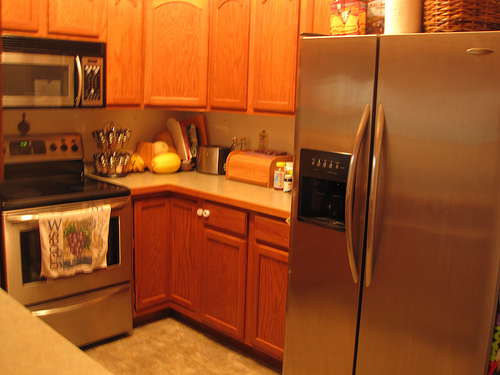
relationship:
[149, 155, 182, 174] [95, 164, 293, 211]
fruit on counter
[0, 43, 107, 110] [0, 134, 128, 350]
microwave above oven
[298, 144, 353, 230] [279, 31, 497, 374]
ice &water dispenser on fridge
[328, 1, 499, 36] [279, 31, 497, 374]
items on top of fridge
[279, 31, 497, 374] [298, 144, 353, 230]
fridge has ice &water dispenser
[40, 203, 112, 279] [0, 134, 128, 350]
towel hanging in front of oven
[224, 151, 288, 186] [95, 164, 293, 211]
bread box on counter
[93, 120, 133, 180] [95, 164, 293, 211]
spice rack on counter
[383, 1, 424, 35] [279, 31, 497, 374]
paper towel on top of fridge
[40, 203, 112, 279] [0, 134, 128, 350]
towel on oven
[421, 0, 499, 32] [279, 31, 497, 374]
basket on top of fridge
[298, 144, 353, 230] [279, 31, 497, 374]
ice &water dispenser on door of fridge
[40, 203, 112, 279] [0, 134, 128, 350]
towel hanging over oven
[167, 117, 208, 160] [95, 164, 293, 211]
papers on counter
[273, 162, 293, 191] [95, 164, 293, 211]
bottles on counter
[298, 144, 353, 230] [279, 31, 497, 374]
ice &water dispenser comes through fridge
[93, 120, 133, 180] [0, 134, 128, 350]
spice rack next to oven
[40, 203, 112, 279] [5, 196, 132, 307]
towel hanging from oven